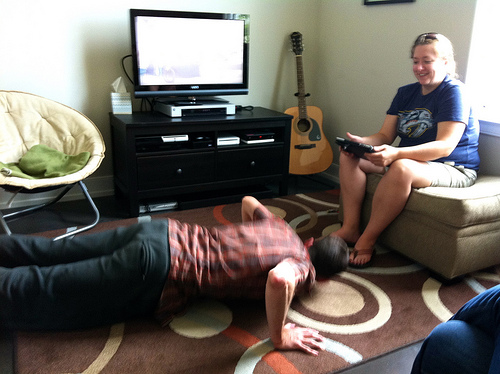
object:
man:
[1, 189, 347, 356]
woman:
[312, 32, 479, 269]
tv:
[120, 4, 254, 118]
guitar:
[281, 31, 333, 175]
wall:
[0, 1, 320, 210]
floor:
[3, 189, 498, 371]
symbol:
[394, 107, 433, 141]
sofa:
[335, 162, 498, 279]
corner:
[304, 39, 327, 60]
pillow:
[0, 143, 95, 180]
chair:
[0, 88, 106, 244]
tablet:
[333, 136, 376, 160]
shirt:
[383, 80, 482, 171]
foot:
[346, 240, 375, 265]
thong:
[353, 254, 358, 257]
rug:
[0, 189, 498, 373]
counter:
[106, 106, 293, 127]